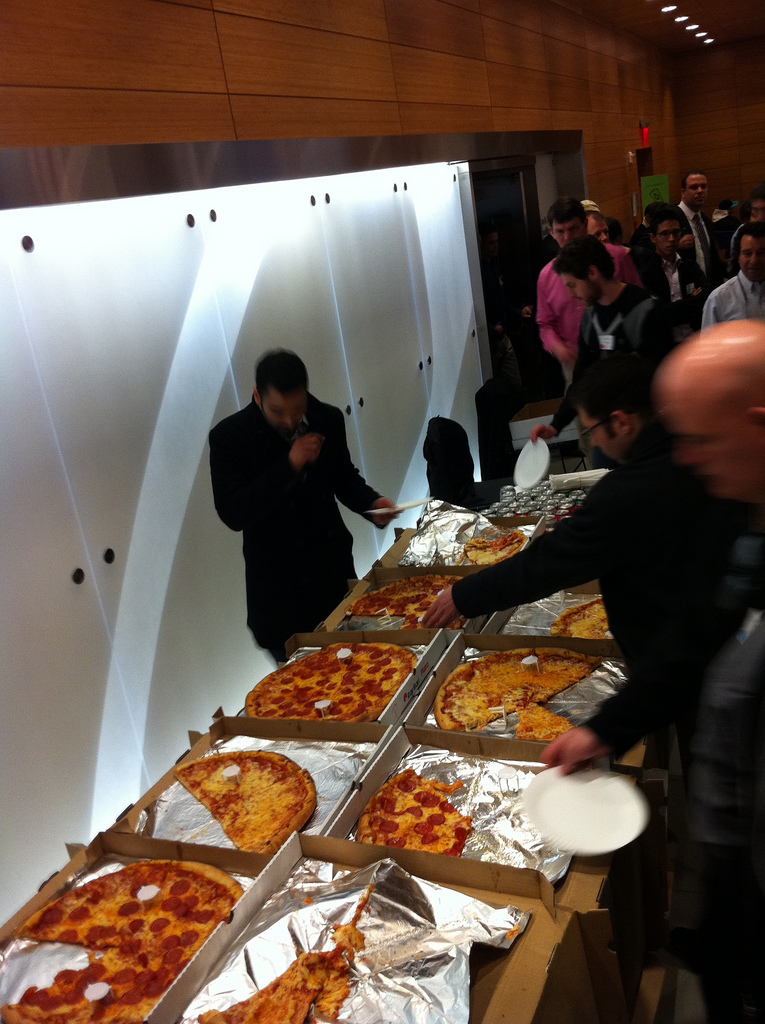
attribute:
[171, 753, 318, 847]
pizza — half gone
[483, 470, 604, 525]
box — of canned beverages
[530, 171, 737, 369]
people — waiting, in line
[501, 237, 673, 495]
person — taking a plate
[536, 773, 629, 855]
plate — white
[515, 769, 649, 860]
plate — white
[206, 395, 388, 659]
suit — black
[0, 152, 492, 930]
wall — white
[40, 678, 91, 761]
wall — white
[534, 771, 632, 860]
plate — round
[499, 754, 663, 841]
plate — white